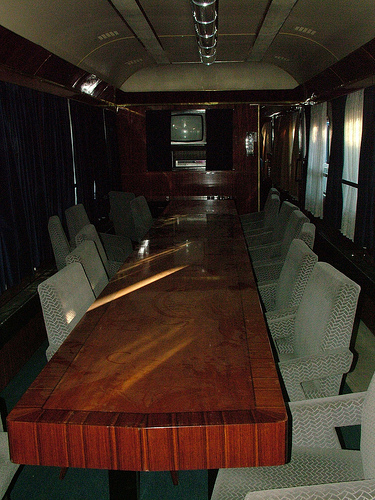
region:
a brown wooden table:
[24, 139, 355, 403]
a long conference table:
[0, 169, 302, 462]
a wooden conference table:
[17, 127, 296, 451]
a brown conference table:
[6, 144, 302, 471]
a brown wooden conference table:
[33, 112, 327, 429]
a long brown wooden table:
[6, 158, 327, 479]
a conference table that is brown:
[71, 168, 298, 487]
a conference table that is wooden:
[40, 180, 290, 484]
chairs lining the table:
[46, 171, 374, 469]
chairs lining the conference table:
[43, 165, 365, 497]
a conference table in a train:
[11, 175, 290, 436]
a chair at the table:
[259, 256, 364, 397]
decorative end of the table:
[8, 410, 295, 470]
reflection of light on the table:
[80, 253, 195, 328]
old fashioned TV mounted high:
[166, 107, 216, 146]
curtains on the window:
[337, 90, 364, 246]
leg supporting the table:
[108, 470, 141, 497]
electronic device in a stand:
[170, 156, 208, 168]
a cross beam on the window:
[334, 177, 364, 190]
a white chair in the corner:
[211, 373, 373, 494]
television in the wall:
[149, 95, 233, 163]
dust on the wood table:
[94, 308, 209, 452]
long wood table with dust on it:
[122, 166, 257, 453]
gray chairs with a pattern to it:
[307, 271, 354, 421]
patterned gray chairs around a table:
[103, 188, 157, 269]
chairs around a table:
[237, 179, 354, 492]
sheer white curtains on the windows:
[301, 97, 336, 227]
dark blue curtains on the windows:
[16, 88, 74, 283]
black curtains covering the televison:
[146, 102, 188, 217]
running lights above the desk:
[178, 3, 224, 78]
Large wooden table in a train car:
[4, 192, 292, 472]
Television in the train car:
[168, 108, 206, 146]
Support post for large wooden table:
[104, 466, 142, 499]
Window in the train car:
[337, 87, 367, 242]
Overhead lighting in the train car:
[188, 0, 223, 70]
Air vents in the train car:
[294, 20, 318, 41]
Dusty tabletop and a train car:
[157, 278, 249, 371]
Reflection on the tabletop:
[159, 210, 210, 277]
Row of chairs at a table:
[246, 186, 358, 381]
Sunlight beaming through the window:
[82, 257, 191, 317]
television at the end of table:
[158, 106, 231, 138]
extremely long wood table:
[32, 180, 292, 475]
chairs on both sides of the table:
[53, 186, 297, 325]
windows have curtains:
[309, 94, 371, 247]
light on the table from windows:
[128, 259, 197, 352]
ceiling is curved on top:
[281, 7, 341, 81]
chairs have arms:
[236, 273, 373, 403]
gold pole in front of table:
[251, 98, 281, 222]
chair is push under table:
[34, 266, 77, 361]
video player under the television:
[173, 157, 212, 174]